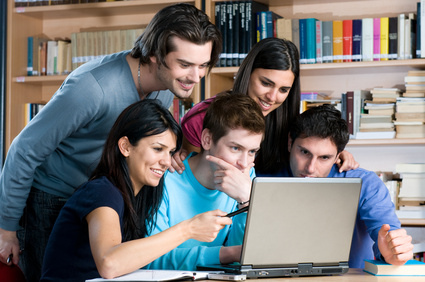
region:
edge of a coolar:
[183, 158, 210, 192]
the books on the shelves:
[12, 0, 423, 265]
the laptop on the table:
[194, 177, 361, 277]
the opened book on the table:
[85, 269, 225, 281]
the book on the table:
[361, 257, 423, 276]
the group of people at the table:
[0, 2, 413, 279]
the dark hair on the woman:
[87, 97, 181, 236]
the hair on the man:
[129, 3, 221, 78]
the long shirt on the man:
[0, 48, 173, 230]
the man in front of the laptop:
[140, 89, 252, 273]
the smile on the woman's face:
[149, 167, 164, 176]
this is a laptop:
[234, 171, 356, 262]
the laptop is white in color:
[262, 199, 285, 217]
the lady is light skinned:
[93, 220, 115, 275]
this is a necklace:
[135, 62, 145, 88]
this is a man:
[73, 6, 225, 89]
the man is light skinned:
[176, 42, 194, 59]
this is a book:
[329, 14, 338, 55]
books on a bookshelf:
[210, 2, 419, 60]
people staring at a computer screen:
[17, 26, 377, 271]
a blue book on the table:
[361, 257, 422, 274]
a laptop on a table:
[239, 175, 355, 267]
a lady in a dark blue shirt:
[65, 124, 164, 242]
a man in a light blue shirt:
[177, 103, 247, 213]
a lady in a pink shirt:
[230, 43, 298, 107]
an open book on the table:
[87, 269, 193, 273]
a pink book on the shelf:
[371, 17, 376, 58]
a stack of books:
[361, 85, 422, 139]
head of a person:
[136, 4, 234, 93]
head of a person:
[114, 92, 197, 178]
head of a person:
[275, 100, 367, 183]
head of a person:
[230, 42, 324, 135]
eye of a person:
[142, 127, 171, 156]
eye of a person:
[225, 122, 263, 154]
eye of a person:
[292, 126, 330, 161]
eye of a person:
[253, 66, 287, 95]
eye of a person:
[172, 43, 212, 72]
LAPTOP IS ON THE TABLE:
[195, 176, 363, 279]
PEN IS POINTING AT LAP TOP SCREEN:
[223, 200, 249, 217]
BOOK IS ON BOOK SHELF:
[361, 17, 372, 59]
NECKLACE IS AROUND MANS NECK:
[138, 61, 161, 102]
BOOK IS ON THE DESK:
[362, 258, 423, 276]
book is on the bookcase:
[305, 17, 315, 63]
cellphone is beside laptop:
[206, 272, 248, 280]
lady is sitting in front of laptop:
[38, 97, 233, 279]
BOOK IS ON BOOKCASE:
[389, 17, 399, 61]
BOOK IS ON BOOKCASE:
[345, 92, 354, 136]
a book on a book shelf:
[299, 14, 311, 64]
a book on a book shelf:
[313, 15, 323, 63]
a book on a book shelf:
[319, 18, 332, 62]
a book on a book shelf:
[328, 17, 346, 61]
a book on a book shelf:
[339, 14, 352, 60]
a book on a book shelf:
[350, 11, 363, 62]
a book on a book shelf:
[359, 15, 374, 61]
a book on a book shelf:
[370, 14, 382, 61]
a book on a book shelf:
[379, 15, 389, 61]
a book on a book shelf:
[388, 12, 397, 58]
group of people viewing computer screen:
[0, 2, 414, 280]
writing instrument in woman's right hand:
[220, 199, 252, 222]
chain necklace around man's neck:
[131, 54, 153, 101]